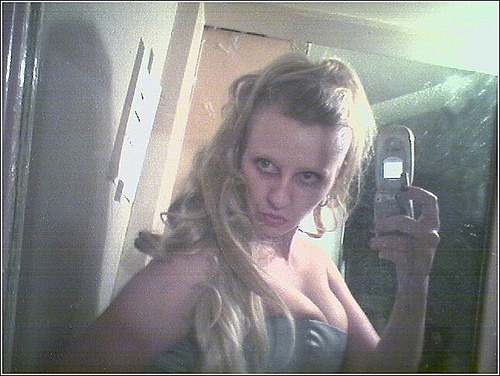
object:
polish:
[395, 186, 407, 194]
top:
[140, 316, 348, 374]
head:
[224, 55, 372, 238]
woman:
[56, 50, 442, 375]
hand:
[368, 185, 440, 279]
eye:
[293, 169, 324, 183]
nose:
[266, 170, 293, 210]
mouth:
[258, 210, 288, 226]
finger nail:
[398, 183, 409, 193]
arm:
[51, 246, 218, 374]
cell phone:
[373, 124, 415, 237]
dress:
[144, 315, 348, 374]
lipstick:
[256, 210, 289, 226]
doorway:
[3, 2, 499, 375]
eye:
[251, 156, 283, 176]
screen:
[380, 155, 404, 180]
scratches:
[424, 82, 484, 125]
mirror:
[305, 43, 497, 375]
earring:
[317, 196, 329, 208]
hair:
[133, 53, 378, 375]